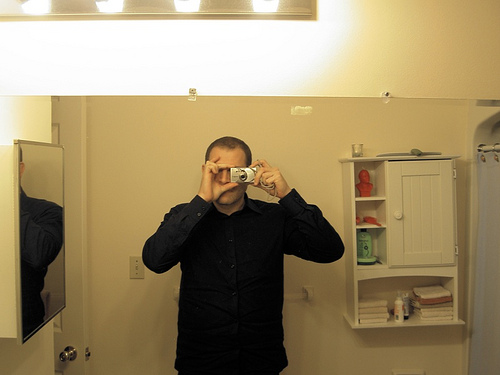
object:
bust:
[356, 167, 374, 197]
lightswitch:
[129, 256, 145, 280]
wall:
[89, 96, 499, 373]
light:
[0, 0, 320, 21]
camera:
[230, 167, 258, 184]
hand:
[248, 159, 286, 197]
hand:
[198, 155, 239, 202]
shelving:
[343, 151, 466, 330]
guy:
[141, 136, 345, 375]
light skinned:
[209, 146, 245, 205]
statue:
[356, 169, 374, 197]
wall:
[0, 17, 499, 93]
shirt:
[141, 188, 345, 375]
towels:
[409, 285, 454, 321]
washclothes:
[337, 135, 498, 334]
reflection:
[18, 146, 64, 339]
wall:
[2, 97, 57, 374]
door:
[384, 159, 457, 268]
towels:
[358, 298, 390, 324]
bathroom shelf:
[339, 154, 469, 328]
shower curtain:
[468, 144, 498, 374]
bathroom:
[5, 3, 497, 375]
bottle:
[394, 297, 404, 324]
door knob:
[59, 346, 78, 363]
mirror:
[16, 141, 66, 342]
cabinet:
[0, 138, 65, 348]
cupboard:
[386, 160, 454, 265]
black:
[139, 188, 346, 375]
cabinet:
[337, 151, 466, 329]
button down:
[229, 238, 233, 241]